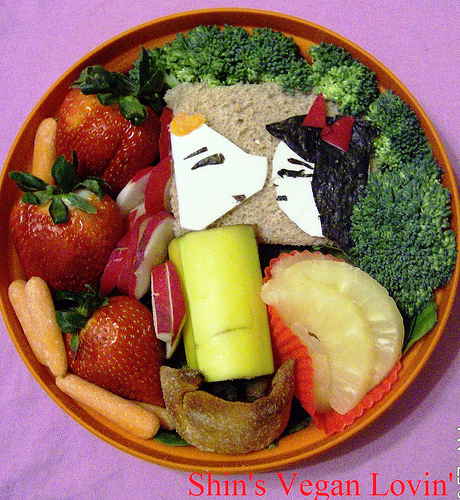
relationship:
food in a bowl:
[7, 29, 455, 449] [4, 7, 458, 482]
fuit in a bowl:
[151, 366, 295, 456] [4, 7, 458, 482]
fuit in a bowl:
[62, 289, 166, 408] [4, 7, 458, 482]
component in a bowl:
[6, 151, 123, 295] [4, 7, 458, 482]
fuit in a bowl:
[50, 80, 137, 187] [4, 7, 458, 482]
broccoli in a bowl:
[350, 165, 457, 317] [4, 7, 458, 482]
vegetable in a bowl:
[289, 50, 397, 140] [4, 7, 458, 482]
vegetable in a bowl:
[146, 28, 294, 87] [4, 7, 458, 482]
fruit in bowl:
[54, 279, 165, 405] [17, 42, 452, 432]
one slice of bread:
[176, 94, 335, 245] [162, 79, 346, 244]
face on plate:
[172, 118, 268, 232] [0, 8, 444, 486]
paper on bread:
[172, 114, 367, 240] [167, 79, 346, 243]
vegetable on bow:
[149, 22, 297, 87] [2, 5, 460, 480]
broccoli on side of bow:
[345, 91, 431, 321] [2, 5, 460, 480]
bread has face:
[162, 79, 346, 244] [272, 139, 327, 238]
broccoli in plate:
[373, 163, 392, 256] [0, 8, 444, 486]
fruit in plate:
[54, 281, 165, 405] [0, 8, 444, 486]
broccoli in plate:
[350, 165, 457, 317] [0, 8, 444, 486]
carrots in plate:
[54, 373, 160, 441] [0, 8, 444, 486]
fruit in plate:
[258, 255, 404, 413] [0, 8, 444, 486]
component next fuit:
[6, 151, 123, 295] [54, 46, 168, 192]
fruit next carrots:
[54, 279, 165, 405] [24, 118, 72, 202]